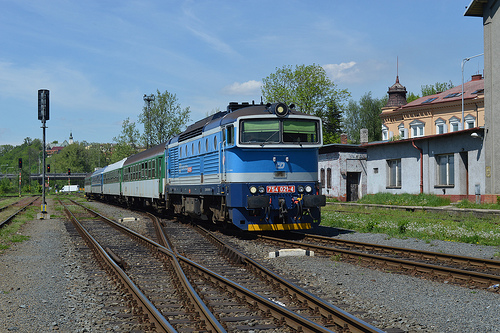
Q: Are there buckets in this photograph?
A: No, there are no buckets.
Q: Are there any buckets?
A: No, there are no buckets.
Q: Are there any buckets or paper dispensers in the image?
A: No, there are no buckets or paper dispensers.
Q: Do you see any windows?
A: Yes, there is a window.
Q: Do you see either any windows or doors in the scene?
A: Yes, there is a window.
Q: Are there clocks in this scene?
A: No, there are no clocks.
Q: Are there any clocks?
A: No, there are no clocks.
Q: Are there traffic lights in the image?
A: Yes, there is a traffic light.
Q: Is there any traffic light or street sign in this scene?
A: Yes, there is a traffic light.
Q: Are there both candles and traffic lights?
A: No, there is a traffic light but no candles.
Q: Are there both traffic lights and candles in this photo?
A: No, there is a traffic light but no candles.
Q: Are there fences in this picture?
A: No, there are no fences.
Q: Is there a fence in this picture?
A: No, there are no fences.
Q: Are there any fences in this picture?
A: No, there are no fences.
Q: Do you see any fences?
A: No, there are no fences.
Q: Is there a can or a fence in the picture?
A: No, there are no fences or cans.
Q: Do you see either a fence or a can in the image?
A: No, there are no fences or cans.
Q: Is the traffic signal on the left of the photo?
A: Yes, the traffic signal is on the left of the image.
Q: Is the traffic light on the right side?
A: No, the traffic light is on the left of the image.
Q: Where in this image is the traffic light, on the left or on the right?
A: The traffic light is on the left of the image.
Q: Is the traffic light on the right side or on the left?
A: The traffic light is on the left of the image.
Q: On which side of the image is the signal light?
A: The signal light is on the left of the image.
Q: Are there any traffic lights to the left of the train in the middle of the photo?
A: Yes, there is a traffic light to the left of the train.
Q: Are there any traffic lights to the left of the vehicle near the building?
A: Yes, there is a traffic light to the left of the train.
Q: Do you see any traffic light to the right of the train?
A: No, the traffic light is to the left of the train.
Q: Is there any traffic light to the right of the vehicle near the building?
A: No, the traffic light is to the left of the train.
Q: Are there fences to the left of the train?
A: No, there is a traffic light to the left of the train.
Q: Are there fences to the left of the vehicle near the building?
A: No, there is a traffic light to the left of the train.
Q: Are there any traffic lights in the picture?
A: Yes, there is a traffic light.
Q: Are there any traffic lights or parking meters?
A: Yes, there is a traffic light.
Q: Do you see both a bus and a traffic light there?
A: No, there is a traffic light but no buses.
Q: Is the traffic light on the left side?
A: Yes, the traffic light is on the left of the image.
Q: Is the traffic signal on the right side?
A: No, the traffic signal is on the left of the image.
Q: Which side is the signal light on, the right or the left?
A: The signal light is on the left of the image.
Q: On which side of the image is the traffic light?
A: The traffic light is on the left of the image.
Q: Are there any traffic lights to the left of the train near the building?
A: Yes, there is a traffic light to the left of the train.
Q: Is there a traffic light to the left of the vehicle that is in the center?
A: Yes, there is a traffic light to the left of the train.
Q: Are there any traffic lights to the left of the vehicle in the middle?
A: Yes, there is a traffic light to the left of the train.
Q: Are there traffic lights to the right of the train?
A: No, the traffic light is to the left of the train.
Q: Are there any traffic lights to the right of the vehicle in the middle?
A: No, the traffic light is to the left of the train.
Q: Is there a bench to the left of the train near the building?
A: No, there is a traffic light to the left of the train.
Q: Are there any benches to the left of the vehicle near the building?
A: No, there is a traffic light to the left of the train.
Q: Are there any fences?
A: No, there are no fences.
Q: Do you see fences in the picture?
A: No, there are no fences.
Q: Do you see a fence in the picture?
A: No, there are no fences.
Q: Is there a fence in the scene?
A: No, there are no fences.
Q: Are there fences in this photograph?
A: No, there are no fences.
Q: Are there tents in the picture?
A: No, there are no tents.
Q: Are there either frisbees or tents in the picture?
A: No, there are no tents or frisbees.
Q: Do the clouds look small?
A: Yes, the clouds are small.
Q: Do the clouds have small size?
A: Yes, the clouds are small.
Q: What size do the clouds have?
A: The clouds have small size.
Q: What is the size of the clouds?
A: The clouds are small.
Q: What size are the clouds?
A: The clouds are small.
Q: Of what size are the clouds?
A: The clouds are small.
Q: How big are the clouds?
A: The clouds are small.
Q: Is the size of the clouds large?
A: No, the clouds are small.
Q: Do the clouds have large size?
A: No, the clouds are small.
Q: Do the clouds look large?
A: No, the clouds are small.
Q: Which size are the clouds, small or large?
A: The clouds are small.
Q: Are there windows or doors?
A: Yes, there is a window.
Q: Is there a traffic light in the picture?
A: Yes, there is a traffic light.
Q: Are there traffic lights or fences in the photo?
A: Yes, there is a traffic light.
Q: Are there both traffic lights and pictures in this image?
A: No, there is a traffic light but no pictures.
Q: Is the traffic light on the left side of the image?
A: Yes, the traffic light is on the left of the image.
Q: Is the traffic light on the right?
A: No, the traffic light is on the left of the image.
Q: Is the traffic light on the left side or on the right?
A: The traffic light is on the left of the image.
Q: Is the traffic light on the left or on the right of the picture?
A: The traffic light is on the left of the image.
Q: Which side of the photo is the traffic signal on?
A: The traffic signal is on the left of the image.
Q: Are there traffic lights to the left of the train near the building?
A: Yes, there is a traffic light to the left of the train.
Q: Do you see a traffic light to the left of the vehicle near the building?
A: Yes, there is a traffic light to the left of the train.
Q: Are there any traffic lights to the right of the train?
A: No, the traffic light is to the left of the train.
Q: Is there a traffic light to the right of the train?
A: No, the traffic light is to the left of the train.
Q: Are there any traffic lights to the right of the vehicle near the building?
A: No, the traffic light is to the left of the train.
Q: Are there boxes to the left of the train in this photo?
A: No, there is a traffic light to the left of the train.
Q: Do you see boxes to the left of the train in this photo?
A: No, there is a traffic light to the left of the train.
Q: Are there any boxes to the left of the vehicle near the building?
A: No, there is a traffic light to the left of the train.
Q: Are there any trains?
A: Yes, there is a train.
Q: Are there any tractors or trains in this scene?
A: Yes, there is a train.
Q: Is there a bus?
A: No, there are no buses.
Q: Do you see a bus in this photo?
A: No, there are no buses.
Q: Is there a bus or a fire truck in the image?
A: No, there are no buses or fire trucks.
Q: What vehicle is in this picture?
A: The vehicle is a train.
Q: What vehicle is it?
A: The vehicle is a train.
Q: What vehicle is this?
A: This is a train.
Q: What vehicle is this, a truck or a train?
A: This is a train.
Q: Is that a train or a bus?
A: That is a train.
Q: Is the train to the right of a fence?
A: No, the train is to the right of a traffic light.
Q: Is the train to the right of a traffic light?
A: Yes, the train is to the right of a traffic light.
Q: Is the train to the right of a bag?
A: No, the train is to the right of a traffic light.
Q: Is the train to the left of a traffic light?
A: No, the train is to the right of a traffic light.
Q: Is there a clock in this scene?
A: No, there are no clocks.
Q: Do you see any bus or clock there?
A: No, there are no clocks or buses.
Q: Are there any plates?
A: Yes, there is a plate.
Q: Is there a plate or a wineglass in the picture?
A: Yes, there is a plate.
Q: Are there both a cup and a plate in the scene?
A: No, there is a plate but no cups.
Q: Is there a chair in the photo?
A: No, there are no chairs.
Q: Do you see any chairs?
A: No, there are no chairs.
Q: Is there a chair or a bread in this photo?
A: No, there are no chairs or breads.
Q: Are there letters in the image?
A: Yes, there are letters.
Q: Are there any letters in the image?
A: Yes, there are letters.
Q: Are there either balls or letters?
A: Yes, there are letters.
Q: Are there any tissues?
A: No, there are no tissues.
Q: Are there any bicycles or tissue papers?
A: No, there are no tissue papers or bicycles.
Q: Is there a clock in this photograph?
A: No, there are no clocks.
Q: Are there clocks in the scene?
A: No, there are no clocks.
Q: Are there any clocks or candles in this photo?
A: No, there are no clocks or candles.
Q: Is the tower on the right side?
A: Yes, the tower is on the right of the image.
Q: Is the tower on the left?
A: No, the tower is on the right of the image.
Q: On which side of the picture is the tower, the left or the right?
A: The tower is on the right of the image.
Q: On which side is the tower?
A: The tower is on the right of the image.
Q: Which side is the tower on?
A: The tower is on the right of the image.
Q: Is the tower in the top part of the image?
A: Yes, the tower is in the top of the image.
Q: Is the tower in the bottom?
A: No, the tower is in the top of the image.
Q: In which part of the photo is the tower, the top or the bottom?
A: The tower is in the top of the image.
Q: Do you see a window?
A: Yes, there are windows.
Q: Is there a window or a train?
A: Yes, there are windows.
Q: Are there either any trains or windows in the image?
A: Yes, there are windows.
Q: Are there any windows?
A: Yes, there is a window.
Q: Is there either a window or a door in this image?
A: Yes, there is a window.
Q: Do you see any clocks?
A: No, there are no clocks.